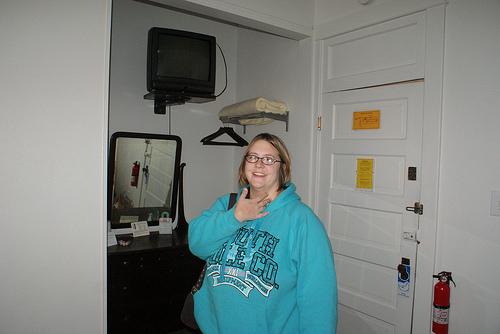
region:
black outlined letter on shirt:
[258, 232, 280, 257]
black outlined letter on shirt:
[251, 230, 262, 250]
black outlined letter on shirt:
[234, 224, 253, 245]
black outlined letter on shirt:
[261, 257, 277, 287]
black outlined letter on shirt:
[248, 249, 263, 276]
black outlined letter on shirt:
[234, 247, 247, 267]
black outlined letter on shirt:
[220, 242, 233, 266]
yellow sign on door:
[348, 109, 382, 130]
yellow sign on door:
[355, 157, 374, 187]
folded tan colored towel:
[218, 95, 282, 125]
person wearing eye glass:
[169, 118, 346, 330]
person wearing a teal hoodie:
[156, 116, 367, 332]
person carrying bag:
[157, 122, 352, 332]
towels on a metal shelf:
[211, 92, 291, 133]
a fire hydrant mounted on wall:
[415, 248, 459, 331]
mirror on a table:
[93, 113, 188, 228]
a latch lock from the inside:
[404, 203, 428, 218]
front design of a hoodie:
[207, 223, 290, 291]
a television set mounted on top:
[132, 19, 228, 106]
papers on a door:
[332, 90, 396, 195]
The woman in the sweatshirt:
[181, 128, 344, 329]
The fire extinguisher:
[424, 267, 460, 332]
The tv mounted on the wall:
[131, 20, 231, 105]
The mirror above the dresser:
[107, 128, 183, 228]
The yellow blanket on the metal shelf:
[218, 96, 288, 127]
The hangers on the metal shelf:
[198, 125, 250, 152]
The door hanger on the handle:
[395, 261, 415, 304]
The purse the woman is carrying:
[175, 262, 210, 331]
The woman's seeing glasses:
[240, 149, 283, 169]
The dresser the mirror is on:
[106, 228, 210, 330]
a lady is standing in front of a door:
[185, 131, 431, 331]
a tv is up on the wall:
[133, 23, 228, 118]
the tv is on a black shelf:
[141, 73, 218, 115]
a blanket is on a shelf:
[216, 95, 296, 134]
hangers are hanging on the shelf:
[198, 112, 249, 149]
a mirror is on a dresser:
[110, 125, 197, 326]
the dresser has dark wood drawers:
[105, 232, 193, 324]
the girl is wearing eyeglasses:
[241, 150, 287, 172]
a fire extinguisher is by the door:
[388, 195, 474, 330]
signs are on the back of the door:
[336, 101, 388, 198]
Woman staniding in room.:
[186, 125, 368, 332]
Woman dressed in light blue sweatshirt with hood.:
[188, 180, 344, 332]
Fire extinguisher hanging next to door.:
[425, 260, 462, 332]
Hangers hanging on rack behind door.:
[195, 113, 252, 152]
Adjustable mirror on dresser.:
[109, 123, 194, 226]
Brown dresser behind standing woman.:
[111, 223, 213, 329]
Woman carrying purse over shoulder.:
[176, 184, 241, 332]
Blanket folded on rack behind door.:
[216, 92, 292, 127]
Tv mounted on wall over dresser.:
[143, 18, 220, 106]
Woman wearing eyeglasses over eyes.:
[238, 147, 290, 169]